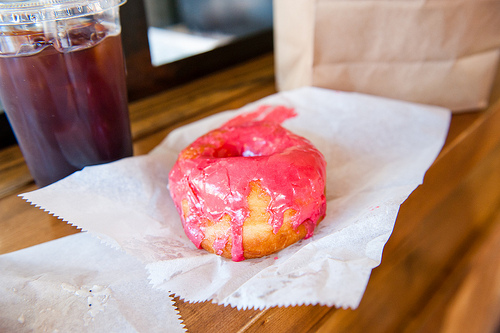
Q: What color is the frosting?
A: Pink.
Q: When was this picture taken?
A: During the day.